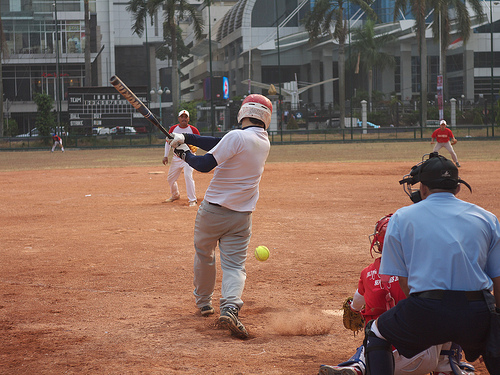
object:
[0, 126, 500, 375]
floor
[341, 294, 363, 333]
glove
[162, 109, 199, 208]
person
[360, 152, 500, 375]
catcher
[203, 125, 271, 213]
t shirt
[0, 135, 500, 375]
park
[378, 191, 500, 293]
shirt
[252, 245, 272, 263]
baseball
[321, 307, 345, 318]
plate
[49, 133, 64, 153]
person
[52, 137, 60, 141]
red shirt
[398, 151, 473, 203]
mask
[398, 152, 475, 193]
hat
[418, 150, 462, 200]
head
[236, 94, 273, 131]
cap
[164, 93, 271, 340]
baseball player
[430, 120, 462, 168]
person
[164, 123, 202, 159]
baseball jersey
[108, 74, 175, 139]
bat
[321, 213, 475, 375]
catcher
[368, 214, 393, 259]
mask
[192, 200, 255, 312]
pants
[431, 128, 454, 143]
baseball jersey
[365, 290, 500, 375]
shorts